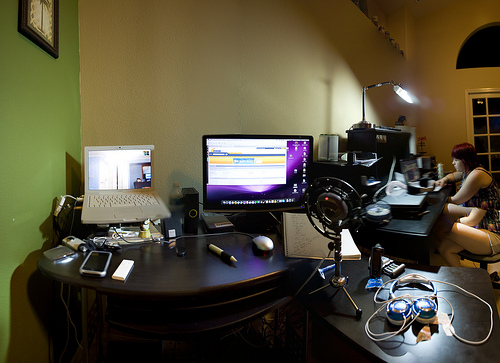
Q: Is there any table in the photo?
A: Yes, there is a table.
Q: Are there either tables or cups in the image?
A: Yes, there is a table.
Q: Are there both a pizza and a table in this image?
A: No, there is a table but no pizzas.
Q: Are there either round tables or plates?
A: Yes, there is a round table.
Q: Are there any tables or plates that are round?
A: Yes, the table is round.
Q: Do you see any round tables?
A: Yes, there is a round table.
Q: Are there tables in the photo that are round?
A: Yes, there is a table that is round.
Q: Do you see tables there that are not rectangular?
A: Yes, there is a round table.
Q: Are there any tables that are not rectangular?
A: Yes, there is a round table.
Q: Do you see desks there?
A: Yes, there is a desk.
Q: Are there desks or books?
A: Yes, there is a desk.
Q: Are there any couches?
A: No, there are no couches.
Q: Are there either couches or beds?
A: No, there are no couches or beds.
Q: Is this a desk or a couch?
A: This is a desk.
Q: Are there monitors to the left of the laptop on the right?
A: Yes, there is a monitor to the left of the laptop.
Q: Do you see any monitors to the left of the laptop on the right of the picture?
A: Yes, there is a monitor to the left of the laptop.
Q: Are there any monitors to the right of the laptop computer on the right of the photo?
A: No, the monitor is to the left of the laptop.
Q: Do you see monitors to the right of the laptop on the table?
A: Yes, there is a monitor to the right of the laptop.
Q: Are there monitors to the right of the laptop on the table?
A: Yes, there is a monitor to the right of the laptop.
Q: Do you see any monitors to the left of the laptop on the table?
A: No, the monitor is to the right of the laptop computer.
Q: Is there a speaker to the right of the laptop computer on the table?
A: No, there is a monitor to the right of the laptop.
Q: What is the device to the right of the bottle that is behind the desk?
A: The device is a monitor.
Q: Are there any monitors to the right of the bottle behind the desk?
A: Yes, there is a monitor to the right of the bottle.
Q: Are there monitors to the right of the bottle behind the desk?
A: Yes, there is a monitor to the right of the bottle.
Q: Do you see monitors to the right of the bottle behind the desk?
A: Yes, there is a monitor to the right of the bottle.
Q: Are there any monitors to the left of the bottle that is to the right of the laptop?
A: No, the monitor is to the right of the bottle.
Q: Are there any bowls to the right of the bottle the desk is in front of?
A: No, there is a monitor to the right of the bottle.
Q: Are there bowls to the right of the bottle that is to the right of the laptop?
A: No, there is a monitor to the right of the bottle.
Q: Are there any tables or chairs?
A: Yes, there is a table.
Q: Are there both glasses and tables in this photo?
A: No, there is a table but no glasses.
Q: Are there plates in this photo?
A: No, there are no plates.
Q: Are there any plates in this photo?
A: No, there are no plates.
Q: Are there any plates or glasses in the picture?
A: No, there are no plates or glasses.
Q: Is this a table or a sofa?
A: This is a table.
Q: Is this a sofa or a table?
A: This is a table.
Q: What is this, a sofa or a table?
A: This is a table.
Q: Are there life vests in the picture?
A: No, there are no life vests.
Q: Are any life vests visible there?
A: No, there are no life vests.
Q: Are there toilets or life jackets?
A: No, there are no life jackets or toilets.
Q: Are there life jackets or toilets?
A: No, there are no life jackets or toilets.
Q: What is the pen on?
A: The pen is on the table.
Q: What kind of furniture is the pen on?
A: The pen is on the table.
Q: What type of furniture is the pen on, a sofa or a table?
A: The pen is on a table.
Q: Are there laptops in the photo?
A: Yes, there is a laptop.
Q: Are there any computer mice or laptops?
A: Yes, there is a laptop.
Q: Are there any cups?
A: No, there are no cups.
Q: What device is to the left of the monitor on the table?
A: The device is a laptop.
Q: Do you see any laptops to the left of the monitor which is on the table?
A: Yes, there is a laptop to the left of the monitor.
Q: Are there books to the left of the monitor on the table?
A: No, there is a laptop to the left of the monitor.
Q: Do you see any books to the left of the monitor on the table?
A: No, there is a laptop to the left of the monitor.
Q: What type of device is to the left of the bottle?
A: The device is a laptop.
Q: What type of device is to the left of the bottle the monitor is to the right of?
A: The device is a laptop.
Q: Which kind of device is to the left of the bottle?
A: The device is a laptop.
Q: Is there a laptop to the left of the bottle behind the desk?
A: Yes, there is a laptop to the left of the bottle.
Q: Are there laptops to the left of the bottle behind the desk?
A: Yes, there is a laptop to the left of the bottle.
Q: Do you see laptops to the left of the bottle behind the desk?
A: Yes, there is a laptop to the left of the bottle.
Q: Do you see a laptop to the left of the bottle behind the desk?
A: Yes, there is a laptop to the left of the bottle.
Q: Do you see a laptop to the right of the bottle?
A: No, the laptop is to the left of the bottle.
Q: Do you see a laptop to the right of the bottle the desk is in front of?
A: No, the laptop is to the left of the bottle.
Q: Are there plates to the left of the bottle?
A: No, there is a laptop to the left of the bottle.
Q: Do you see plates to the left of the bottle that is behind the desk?
A: No, there is a laptop to the left of the bottle.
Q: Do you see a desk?
A: Yes, there is a desk.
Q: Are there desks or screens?
A: Yes, there is a desk.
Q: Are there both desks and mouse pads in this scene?
A: No, there is a desk but no mouse pads.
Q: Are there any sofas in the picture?
A: No, there are no sofas.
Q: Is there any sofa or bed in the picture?
A: No, there are no sofas or beds.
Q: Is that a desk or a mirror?
A: That is a desk.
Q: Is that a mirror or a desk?
A: That is a desk.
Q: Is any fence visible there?
A: No, there are no fences.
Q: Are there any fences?
A: No, there are no fences.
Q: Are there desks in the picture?
A: Yes, there is a desk.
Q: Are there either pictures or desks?
A: Yes, there is a desk.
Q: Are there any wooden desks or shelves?
A: Yes, there is a wood desk.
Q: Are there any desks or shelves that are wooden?
A: Yes, the desk is wooden.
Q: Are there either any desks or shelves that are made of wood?
A: Yes, the desk is made of wood.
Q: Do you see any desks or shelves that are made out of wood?
A: Yes, the desk is made of wood.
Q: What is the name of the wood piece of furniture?
A: The piece of furniture is a desk.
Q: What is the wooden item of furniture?
A: The piece of furniture is a desk.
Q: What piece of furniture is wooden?
A: The piece of furniture is a desk.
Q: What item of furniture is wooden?
A: The piece of furniture is a desk.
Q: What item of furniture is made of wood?
A: The piece of furniture is a desk.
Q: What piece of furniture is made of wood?
A: The piece of furniture is a desk.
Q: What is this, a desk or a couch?
A: This is a desk.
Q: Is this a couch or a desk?
A: This is a desk.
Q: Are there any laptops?
A: Yes, there is a laptop.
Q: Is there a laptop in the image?
A: Yes, there is a laptop.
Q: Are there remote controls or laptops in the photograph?
A: Yes, there is a laptop.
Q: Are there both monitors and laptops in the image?
A: Yes, there are both a laptop and a monitor.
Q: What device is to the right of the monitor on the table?
A: The device is a laptop.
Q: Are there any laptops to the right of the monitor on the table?
A: Yes, there is a laptop to the right of the monitor.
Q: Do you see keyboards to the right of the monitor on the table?
A: No, there is a laptop to the right of the monitor.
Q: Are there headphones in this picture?
A: Yes, there are headphones.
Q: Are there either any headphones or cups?
A: Yes, there are headphones.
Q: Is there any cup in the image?
A: No, there are no cups.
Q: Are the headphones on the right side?
A: Yes, the headphones are on the right of the image.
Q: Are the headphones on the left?
A: No, the headphones are on the right of the image.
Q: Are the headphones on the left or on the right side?
A: The headphones are on the right of the image.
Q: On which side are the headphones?
A: The headphones are on the right of the image.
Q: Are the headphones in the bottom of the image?
A: Yes, the headphones are in the bottom of the image.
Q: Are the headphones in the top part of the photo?
A: No, the headphones are in the bottom of the image.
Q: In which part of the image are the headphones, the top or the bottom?
A: The headphones are in the bottom of the image.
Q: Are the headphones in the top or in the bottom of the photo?
A: The headphones are in the bottom of the image.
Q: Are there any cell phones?
A: Yes, there is a cell phone.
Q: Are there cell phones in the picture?
A: Yes, there is a cell phone.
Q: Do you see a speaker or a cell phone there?
A: Yes, there is a cell phone.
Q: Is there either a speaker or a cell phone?
A: Yes, there is a cell phone.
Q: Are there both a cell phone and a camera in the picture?
A: No, there is a cell phone but no cameras.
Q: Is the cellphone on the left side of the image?
A: Yes, the cellphone is on the left of the image.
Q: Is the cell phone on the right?
A: No, the cell phone is on the left of the image.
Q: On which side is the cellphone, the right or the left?
A: The cellphone is on the left of the image.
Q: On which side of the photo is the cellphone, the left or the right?
A: The cellphone is on the left of the image.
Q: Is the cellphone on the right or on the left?
A: The cellphone is on the left of the image.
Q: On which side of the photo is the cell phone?
A: The cell phone is on the left of the image.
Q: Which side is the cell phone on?
A: The cell phone is on the left of the image.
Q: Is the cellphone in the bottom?
A: Yes, the cellphone is in the bottom of the image.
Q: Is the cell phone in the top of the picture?
A: No, the cell phone is in the bottom of the image.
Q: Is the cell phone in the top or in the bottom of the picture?
A: The cell phone is in the bottom of the image.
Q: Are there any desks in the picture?
A: Yes, there is a desk.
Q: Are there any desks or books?
A: Yes, there is a desk.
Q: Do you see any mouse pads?
A: No, there are no mouse pads.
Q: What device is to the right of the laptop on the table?
A: The device is a monitor.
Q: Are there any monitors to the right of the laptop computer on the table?
A: Yes, there is a monitor to the right of the laptop computer.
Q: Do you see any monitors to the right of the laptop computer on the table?
A: Yes, there is a monitor to the right of the laptop computer.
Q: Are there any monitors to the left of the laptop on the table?
A: No, the monitor is to the right of the laptop.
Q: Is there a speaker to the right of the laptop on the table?
A: No, there is a monitor to the right of the laptop.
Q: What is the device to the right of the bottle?
A: The device is a monitor.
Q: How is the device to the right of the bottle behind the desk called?
A: The device is a monitor.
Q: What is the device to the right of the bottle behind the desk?
A: The device is a monitor.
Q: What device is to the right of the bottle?
A: The device is a monitor.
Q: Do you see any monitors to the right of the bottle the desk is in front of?
A: Yes, there is a monitor to the right of the bottle.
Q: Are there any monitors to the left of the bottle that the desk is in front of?
A: No, the monitor is to the right of the bottle.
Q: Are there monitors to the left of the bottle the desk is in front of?
A: No, the monitor is to the right of the bottle.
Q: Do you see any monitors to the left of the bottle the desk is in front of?
A: No, the monitor is to the right of the bottle.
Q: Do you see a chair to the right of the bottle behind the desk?
A: No, there is a monitor to the right of the bottle.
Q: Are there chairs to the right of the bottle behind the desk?
A: No, there is a monitor to the right of the bottle.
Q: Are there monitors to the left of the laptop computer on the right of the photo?
A: Yes, there is a monitor to the left of the laptop.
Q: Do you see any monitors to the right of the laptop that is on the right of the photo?
A: No, the monitor is to the left of the laptop.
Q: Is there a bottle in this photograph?
A: Yes, there is a bottle.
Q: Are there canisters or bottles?
A: Yes, there is a bottle.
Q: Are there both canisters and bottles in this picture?
A: No, there is a bottle but no canisters.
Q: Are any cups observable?
A: No, there are no cups.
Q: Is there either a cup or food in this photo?
A: No, there are no cups or food.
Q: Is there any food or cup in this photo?
A: No, there are no cups or food.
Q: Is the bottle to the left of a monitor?
A: Yes, the bottle is to the left of a monitor.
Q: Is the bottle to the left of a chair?
A: No, the bottle is to the left of a monitor.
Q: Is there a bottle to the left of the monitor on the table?
A: Yes, there is a bottle to the left of the monitor.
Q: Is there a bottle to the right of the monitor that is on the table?
A: No, the bottle is to the left of the monitor.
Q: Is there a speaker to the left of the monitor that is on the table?
A: No, there is a bottle to the left of the monitor.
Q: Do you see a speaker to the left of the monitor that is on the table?
A: No, there is a bottle to the left of the monitor.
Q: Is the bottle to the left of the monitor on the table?
A: Yes, the bottle is to the left of the monitor.